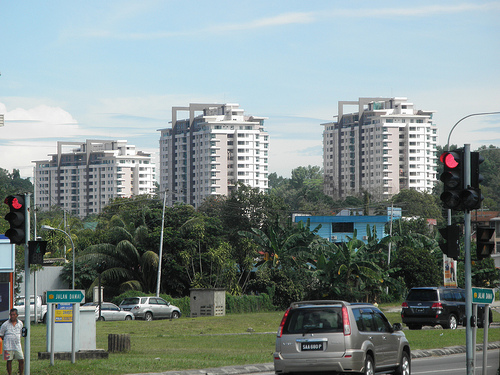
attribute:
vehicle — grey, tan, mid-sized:
[265, 290, 417, 375]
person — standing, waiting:
[3, 306, 37, 375]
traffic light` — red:
[6, 189, 32, 249]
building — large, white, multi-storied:
[154, 97, 272, 201]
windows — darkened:
[287, 308, 396, 333]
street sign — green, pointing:
[39, 288, 88, 307]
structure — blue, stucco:
[289, 208, 410, 249]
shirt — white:
[1, 319, 30, 350]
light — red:
[1, 193, 27, 209]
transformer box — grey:
[185, 282, 230, 318]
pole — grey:
[20, 188, 34, 375]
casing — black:
[439, 147, 488, 211]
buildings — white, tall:
[18, 96, 448, 207]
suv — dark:
[399, 279, 496, 330]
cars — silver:
[83, 287, 186, 323]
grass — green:
[141, 333, 250, 373]